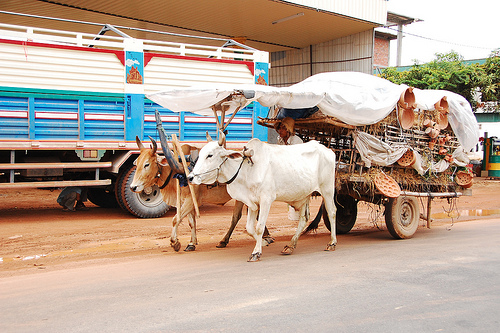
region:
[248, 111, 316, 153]
Funny hat pulled down low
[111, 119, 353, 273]
Oxen pulling the wagon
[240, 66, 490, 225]
Selling a variety of goods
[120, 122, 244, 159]
Pointy horns on their heads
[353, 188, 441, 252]
Muddy wheel on the cart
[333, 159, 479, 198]
Hay lines the wagon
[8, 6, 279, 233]
Heavy duty truck parked on side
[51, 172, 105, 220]
Person underneath the truck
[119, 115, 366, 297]
One ox is white the other brown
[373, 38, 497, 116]
Green trees behind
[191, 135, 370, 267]
White cow walking down a street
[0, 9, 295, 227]
red white and blue truck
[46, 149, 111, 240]
guy under a truck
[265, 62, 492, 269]
cart with a guy driving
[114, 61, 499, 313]
cart being pulled by two cows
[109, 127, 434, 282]
brown and white cow pulling a cart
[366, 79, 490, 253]
cart carrying pottery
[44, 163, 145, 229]
guy under truck fixing it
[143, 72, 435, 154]
covering over a cart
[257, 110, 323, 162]
guy driving cart with a hat on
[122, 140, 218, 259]
A TAN COW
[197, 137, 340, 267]
A WHITE COW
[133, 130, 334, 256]
A PAIR OF COWS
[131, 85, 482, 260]
COWS PULLING A WAGON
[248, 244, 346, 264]
3 COW HOOVES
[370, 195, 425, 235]
WAGON WHEELS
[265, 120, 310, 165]
MAN IN WAGON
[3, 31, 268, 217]
A COLORFUL TRUCK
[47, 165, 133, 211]
MAN WORKING UNDER TRUCK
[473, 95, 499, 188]
A COLORFUL BUILDING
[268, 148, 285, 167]
the cow is white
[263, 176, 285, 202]
the cow is white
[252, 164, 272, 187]
the cow is white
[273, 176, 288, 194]
the cow is white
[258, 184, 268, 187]
the cow is white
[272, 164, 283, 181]
the cow is white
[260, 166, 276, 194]
the cow is white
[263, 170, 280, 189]
the cow is white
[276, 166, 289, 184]
the cow is white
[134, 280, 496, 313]
The road is dirty.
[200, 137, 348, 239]
The cow is white.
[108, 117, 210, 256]
The cow is brown.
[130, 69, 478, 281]
The cows are pulling a cart.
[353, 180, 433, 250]
The wheel is brown.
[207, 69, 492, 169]
The cloth is white.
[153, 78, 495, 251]
The wagon is full.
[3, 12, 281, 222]
The cart is parked.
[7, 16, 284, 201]
The cart is white and blue.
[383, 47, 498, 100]
The trees are green.